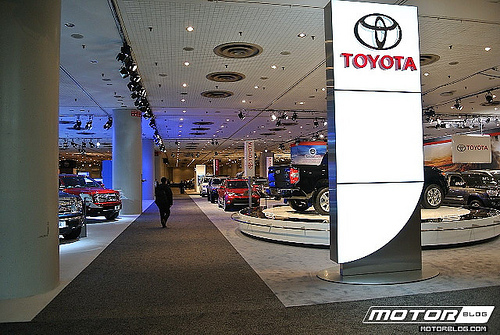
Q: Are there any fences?
A: No, there are no fences.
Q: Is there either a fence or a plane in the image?
A: No, there are no fences or airplanes.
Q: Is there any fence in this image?
A: No, there are no fences.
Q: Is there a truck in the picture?
A: Yes, there is a truck.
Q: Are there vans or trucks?
A: Yes, there is a truck.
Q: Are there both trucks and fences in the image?
A: No, there is a truck but no fences.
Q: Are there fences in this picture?
A: No, there are no fences.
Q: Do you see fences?
A: No, there are no fences.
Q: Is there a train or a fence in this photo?
A: No, there are no fences or trains.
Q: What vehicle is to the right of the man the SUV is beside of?
A: The vehicle is a truck.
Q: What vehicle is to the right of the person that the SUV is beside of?
A: The vehicle is a truck.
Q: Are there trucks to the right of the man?
A: Yes, there is a truck to the right of the man.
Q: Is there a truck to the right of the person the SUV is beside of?
A: Yes, there is a truck to the right of the man.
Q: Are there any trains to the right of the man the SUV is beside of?
A: No, there is a truck to the right of the man.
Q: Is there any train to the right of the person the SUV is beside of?
A: No, there is a truck to the right of the man.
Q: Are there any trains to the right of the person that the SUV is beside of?
A: No, there is a truck to the right of the man.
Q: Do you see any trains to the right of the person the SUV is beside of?
A: No, there is a truck to the right of the man.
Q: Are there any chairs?
A: No, there are no chairs.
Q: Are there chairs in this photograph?
A: No, there are no chairs.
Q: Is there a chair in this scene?
A: No, there are no chairs.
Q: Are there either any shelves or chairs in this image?
A: No, there are no chairs or shelves.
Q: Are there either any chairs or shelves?
A: No, there are no chairs or shelves.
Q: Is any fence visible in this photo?
A: No, there are no fences.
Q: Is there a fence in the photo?
A: No, there are no fences.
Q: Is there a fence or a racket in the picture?
A: No, there are no fences or rackets.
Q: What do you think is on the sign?
A: The logo is on the sign.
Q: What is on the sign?
A: The logo is on the sign.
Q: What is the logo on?
A: The logo is on the sign.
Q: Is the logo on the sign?
A: Yes, the logo is on the sign.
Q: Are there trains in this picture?
A: No, there are no trains.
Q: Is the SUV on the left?
A: Yes, the SUV is on the left of the image.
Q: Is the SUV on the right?
A: No, the SUV is on the left of the image.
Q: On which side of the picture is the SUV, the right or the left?
A: The SUV is on the left of the image.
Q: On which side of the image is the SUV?
A: The SUV is on the left of the image.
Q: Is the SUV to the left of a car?
A: Yes, the SUV is to the left of a car.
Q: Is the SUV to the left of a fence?
A: No, the SUV is to the left of a car.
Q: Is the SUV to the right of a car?
A: No, the SUV is to the left of a car.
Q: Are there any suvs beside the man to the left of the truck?
A: Yes, there is a SUV beside the man.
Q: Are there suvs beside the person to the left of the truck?
A: Yes, there is a SUV beside the man.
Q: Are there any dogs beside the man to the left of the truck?
A: No, there is a SUV beside the man.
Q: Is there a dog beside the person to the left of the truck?
A: No, there is a SUV beside the man.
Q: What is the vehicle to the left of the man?
A: The vehicle is a SUV.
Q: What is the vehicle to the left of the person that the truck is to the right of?
A: The vehicle is a SUV.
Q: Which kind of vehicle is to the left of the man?
A: The vehicle is a SUV.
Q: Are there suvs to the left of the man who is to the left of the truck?
A: Yes, there is a SUV to the left of the man.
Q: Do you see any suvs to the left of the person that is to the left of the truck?
A: Yes, there is a SUV to the left of the man.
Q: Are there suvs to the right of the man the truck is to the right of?
A: No, the SUV is to the left of the man.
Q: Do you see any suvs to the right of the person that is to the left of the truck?
A: No, the SUV is to the left of the man.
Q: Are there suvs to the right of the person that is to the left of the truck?
A: No, the SUV is to the left of the man.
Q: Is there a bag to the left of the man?
A: No, there is a SUV to the left of the man.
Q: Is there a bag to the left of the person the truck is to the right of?
A: No, there is a SUV to the left of the man.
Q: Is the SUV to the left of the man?
A: Yes, the SUV is to the left of the man.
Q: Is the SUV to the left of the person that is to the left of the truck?
A: Yes, the SUV is to the left of the man.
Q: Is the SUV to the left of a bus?
A: No, the SUV is to the left of the man.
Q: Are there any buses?
A: No, there are no buses.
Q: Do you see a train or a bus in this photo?
A: No, there are no buses or trains.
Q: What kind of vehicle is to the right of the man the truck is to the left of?
A: The vehicles are cars.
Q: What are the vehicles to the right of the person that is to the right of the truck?
A: The vehicles are cars.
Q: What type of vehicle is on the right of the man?
A: The vehicles are cars.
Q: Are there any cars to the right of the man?
A: Yes, there are cars to the right of the man.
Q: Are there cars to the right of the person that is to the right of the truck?
A: Yes, there are cars to the right of the man.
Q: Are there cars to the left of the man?
A: No, the cars are to the right of the man.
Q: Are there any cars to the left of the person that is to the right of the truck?
A: No, the cars are to the right of the man.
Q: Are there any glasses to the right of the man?
A: No, there are cars to the right of the man.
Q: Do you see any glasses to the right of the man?
A: No, there are cars to the right of the man.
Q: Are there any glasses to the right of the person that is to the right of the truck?
A: No, there are cars to the right of the man.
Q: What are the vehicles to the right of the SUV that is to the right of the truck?
A: The vehicles are cars.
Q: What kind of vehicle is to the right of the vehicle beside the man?
A: The vehicles are cars.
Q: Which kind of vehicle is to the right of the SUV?
A: The vehicles are cars.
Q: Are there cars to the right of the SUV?
A: Yes, there are cars to the right of the SUV.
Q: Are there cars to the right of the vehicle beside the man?
A: Yes, there are cars to the right of the SUV.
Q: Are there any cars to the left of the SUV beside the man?
A: No, the cars are to the right of the SUV.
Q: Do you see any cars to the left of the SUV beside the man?
A: No, the cars are to the right of the SUV.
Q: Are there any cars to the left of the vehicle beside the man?
A: No, the cars are to the right of the SUV.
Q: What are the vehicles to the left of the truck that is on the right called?
A: The vehicles are cars.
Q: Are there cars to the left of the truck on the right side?
A: Yes, there are cars to the left of the truck.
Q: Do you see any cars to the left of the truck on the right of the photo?
A: Yes, there are cars to the left of the truck.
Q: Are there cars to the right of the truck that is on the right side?
A: No, the cars are to the left of the truck.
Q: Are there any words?
A: Yes, there are words.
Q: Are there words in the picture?
A: Yes, there are words.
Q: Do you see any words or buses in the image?
A: Yes, there are words.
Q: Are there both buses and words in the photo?
A: No, there are words but no buses.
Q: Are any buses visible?
A: No, there are no buses.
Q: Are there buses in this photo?
A: No, there are no buses.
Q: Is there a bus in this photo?
A: No, there are no buses.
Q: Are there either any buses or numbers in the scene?
A: No, there are no buses or numbers.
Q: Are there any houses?
A: No, there are no houses.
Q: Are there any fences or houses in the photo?
A: No, there are no houses or fences.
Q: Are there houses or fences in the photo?
A: No, there are no houses or fences.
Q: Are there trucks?
A: Yes, there is a truck.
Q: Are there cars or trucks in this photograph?
A: Yes, there is a truck.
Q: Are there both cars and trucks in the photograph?
A: Yes, there are both a truck and a car.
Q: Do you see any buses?
A: No, there are no buses.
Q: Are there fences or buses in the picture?
A: No, there are no buses or fences.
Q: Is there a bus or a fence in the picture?
A: No, there are no buses or fences.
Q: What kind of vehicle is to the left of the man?
A: The vehicle is a truck.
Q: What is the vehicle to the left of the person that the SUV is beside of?
A: The vehicle is a truck.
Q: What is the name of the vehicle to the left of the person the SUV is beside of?
A: The vehicle is a truck.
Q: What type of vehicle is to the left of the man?
A: The vehicle is a truck.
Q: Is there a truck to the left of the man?
A: Yes, there is a truck to the left of the man.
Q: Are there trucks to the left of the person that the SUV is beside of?
A: Yes, there is a truck to the left of the man.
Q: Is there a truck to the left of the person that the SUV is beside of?
A: Yes, there is a truck to the left of the man.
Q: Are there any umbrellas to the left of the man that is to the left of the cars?
A: No, there is a truck to the left of the man.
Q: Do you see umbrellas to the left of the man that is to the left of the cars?
A: No, there is a truck to the left of the man.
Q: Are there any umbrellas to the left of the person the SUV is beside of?
A: No, there is a truck to the left of the man.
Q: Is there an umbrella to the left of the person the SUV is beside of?
A: No, there is a truck to the left of the man.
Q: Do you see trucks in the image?
A: Yes, there is a truck.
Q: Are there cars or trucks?
A: Yes, there is a truck.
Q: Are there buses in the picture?
A: No, there are no buses.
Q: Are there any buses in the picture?
A: No, there are no buses.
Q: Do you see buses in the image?
A: No, there are no buses.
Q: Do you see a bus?
A: No, there are no buses.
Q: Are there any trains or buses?
A: No, there are no buses or trains.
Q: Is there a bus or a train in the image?
A: No, there are no buses or trains.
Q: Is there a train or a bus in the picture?
A: No, there are no buses or trains.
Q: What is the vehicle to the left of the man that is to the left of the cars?
A: The vehicle is a truck.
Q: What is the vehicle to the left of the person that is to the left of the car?
A: The vehicle is a truck.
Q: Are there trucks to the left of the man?
A: Yes, there is a truck to the left of the man.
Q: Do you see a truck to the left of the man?
A: Yes, there is a truck to the left of the man.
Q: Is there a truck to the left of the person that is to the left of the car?
A: Yes, there is a truck to the left of the man.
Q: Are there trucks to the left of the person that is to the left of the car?
A: Yes, there is a truck to the left of the man.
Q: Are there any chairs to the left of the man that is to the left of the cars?
A: No, there is a truck to the left of the man.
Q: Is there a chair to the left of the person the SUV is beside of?
A: No, there is a truck to the left of the man.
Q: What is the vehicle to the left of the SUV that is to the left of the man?
A: The vehicle is a truck.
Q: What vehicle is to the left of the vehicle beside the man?
A: The vehicle is a truck.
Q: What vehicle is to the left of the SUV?
A: The vehicle is a truck.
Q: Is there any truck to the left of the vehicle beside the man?
A: Yes, there is a truck to the left of the SUV.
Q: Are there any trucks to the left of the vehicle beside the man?
A: Yes, there is a truck to the left of the SUV.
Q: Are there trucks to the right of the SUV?
A: No, the truck is to the left of the SUV.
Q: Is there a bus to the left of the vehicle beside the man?
A: No, there is a truck to the left of the SUV.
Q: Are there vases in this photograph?
A: No, there are no vases.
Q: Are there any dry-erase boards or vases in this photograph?
A: No, there are no vases or dry-erase boards.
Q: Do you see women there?
A: No, there are no women.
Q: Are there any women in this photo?
A: No, there are no women.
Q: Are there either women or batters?
A: No, there are no women or batters.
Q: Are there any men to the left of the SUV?
A: No, the man is to the right of the SUV.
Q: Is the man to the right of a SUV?
A: Yes, the man is to the right of a SUV.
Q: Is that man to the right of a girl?
A: No, the man is to the right of a SUV.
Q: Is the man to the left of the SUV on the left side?
A: No, the man is to the right of the SUV.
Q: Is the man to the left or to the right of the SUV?
A: The man is to the right of the SUV.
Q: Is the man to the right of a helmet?
A: No, the man is to the right of a truck.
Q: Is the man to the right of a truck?
A: Yes, the man is to the right of a truck.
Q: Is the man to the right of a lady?
A: No, the man is to the right of a truck.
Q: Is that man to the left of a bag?
A: No, the man is to the left of the car.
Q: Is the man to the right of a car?
A: No, the man is to the left of a car.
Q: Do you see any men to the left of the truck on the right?
A: Yes, there is a man to the left of the truck.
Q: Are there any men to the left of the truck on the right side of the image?
A: Yes, there is a man to the left of the truck.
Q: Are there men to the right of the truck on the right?
A: No, the man is to the left of the truck.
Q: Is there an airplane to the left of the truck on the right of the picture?
A: No, there is a man to the left of the truck.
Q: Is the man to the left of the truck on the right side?
A: Yes, the man is to the left of the truck.